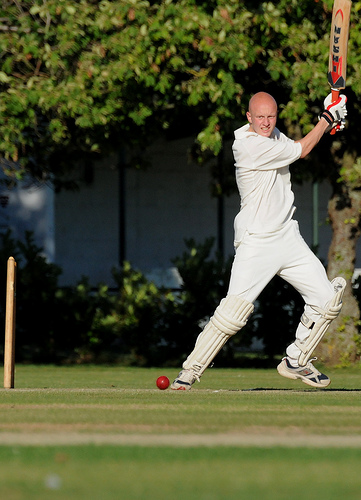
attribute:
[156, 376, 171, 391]
ball — red, small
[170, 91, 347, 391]
man — standing, bald, tall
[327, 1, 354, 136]
stick — large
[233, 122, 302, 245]
shirt — white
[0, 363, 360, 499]
grass — green, lush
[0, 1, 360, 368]
tree — large, green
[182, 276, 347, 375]
shin guards — white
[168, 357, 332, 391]
shoes — white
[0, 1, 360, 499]
field — green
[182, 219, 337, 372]
pants — white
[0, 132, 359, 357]
wall — white